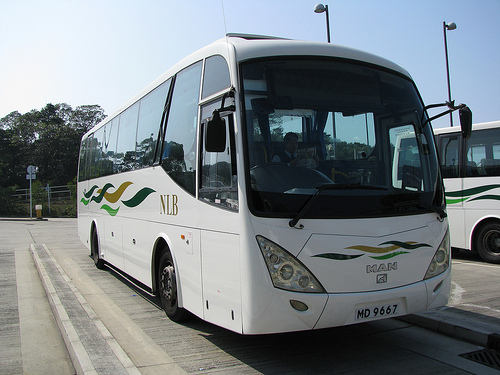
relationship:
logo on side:
[154, 191, 182, 218] [76, 52, 243, 325]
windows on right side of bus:
[122, 67, 202, 162] [67, 27, 479, 341]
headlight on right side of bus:
[254, 234, 324, 293] [73, 33, 449, 341]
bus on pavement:
[67, 27, 479, 341] [1, 223, 81, 373]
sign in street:
[23, 157, 40, 197] [12, 222, 61, 254]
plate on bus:
[354, 302, 398, 320] [67, 27, 479, 341]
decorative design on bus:
[80, 180, 157, 217] [67, 27, 479, 341]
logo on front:
[364, 259, 403, 274] [228, 40, 448, 329]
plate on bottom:
[332, 286, 424, 338] [224, 276, 463, 336]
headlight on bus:
[255, 234, 329, 293] [67, 27, 479, 341]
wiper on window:
[282, 205, 341, 225] [246, 69, 436, 209]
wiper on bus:
[282, 205, 341, 225] [67, 27, 479, 341]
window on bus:
[149, 63, 213, 203] [67, 27, 479, 341]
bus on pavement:
[390, 111, 497, 255] [2, 220, 499, 368]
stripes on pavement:
[24, 231, 152, 372] [2, 220, 499, 368]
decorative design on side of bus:
[80, 180, 152, 218] [73, 33, 449, 341]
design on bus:
[314, 232, 489, 264] [47, 28, 480, 358]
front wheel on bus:
[158, 251, 183, 322] [67, 27, 479, 341]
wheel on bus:
[75, 204, 104, 277] [67, 27, 479, 341]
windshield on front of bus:
[226, 64, 431, 224] [47, 28, 480, 358]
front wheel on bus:
[155, 248, 195, 323] [73, 33, 449, 341]